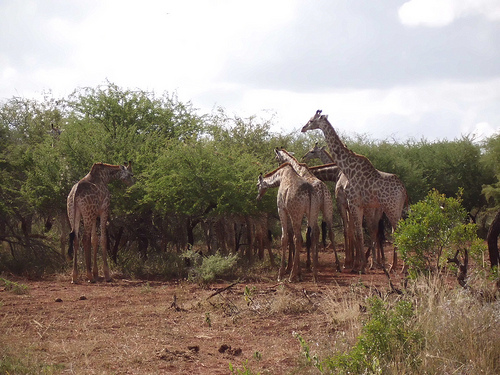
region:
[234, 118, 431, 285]
Giraffes in the wilderness.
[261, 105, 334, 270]
The giraffee is eating from tree.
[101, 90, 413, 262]
Trees around the giraffes.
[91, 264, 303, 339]
The ground is dry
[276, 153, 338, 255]
The giraffe is brown and white.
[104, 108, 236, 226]
The trees is green.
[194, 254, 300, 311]
Branches on the ground.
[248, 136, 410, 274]
Giraffes standing in a group.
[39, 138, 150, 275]
One giraffe standing alone.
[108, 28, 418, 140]
The clouds are white.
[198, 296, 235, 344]
part of a ground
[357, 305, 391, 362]
part of a plant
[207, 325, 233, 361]
part of a stone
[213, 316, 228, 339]
part of a ground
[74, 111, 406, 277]
Giraffes by the trees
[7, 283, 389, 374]
A patch of dirt in front of the giraffes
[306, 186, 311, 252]
The tail of the giraffe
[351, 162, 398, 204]
The giraffe has brown and white spots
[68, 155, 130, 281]
A giraffe eating leaves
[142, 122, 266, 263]
Trees near the giraffes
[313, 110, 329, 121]
The ears of the giraffe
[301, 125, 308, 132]
The nose of the giraffe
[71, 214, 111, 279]
The legs of the giraffe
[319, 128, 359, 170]
The giraffe has a long neck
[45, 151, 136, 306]
brown and beige giraffe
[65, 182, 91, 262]
tail on a giraffe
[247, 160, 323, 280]
brown and beige giraffe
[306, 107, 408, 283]
brown and beige giraffe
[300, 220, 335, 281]
leg of a giraffe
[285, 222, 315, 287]
leg of a giraffe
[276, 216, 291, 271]
leg on a giraffe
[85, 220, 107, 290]
leg of a giraffe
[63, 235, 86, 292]
leg of a giraffe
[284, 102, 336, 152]
face of a giraffe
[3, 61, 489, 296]
giraffes in front of row of trees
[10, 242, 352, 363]
brown dirt with branches and yellow growth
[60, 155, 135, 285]
giraffe with angle and curve on back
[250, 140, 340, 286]
giraffes with necks bent forward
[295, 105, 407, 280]
giraffe with head held up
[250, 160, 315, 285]
giraffe feeding from tree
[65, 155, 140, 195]
giraffe with head deep into tree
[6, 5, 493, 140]
light blue sky with wide white clouds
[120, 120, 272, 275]
thin and dark trunks of trees being eaten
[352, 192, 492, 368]
bush with green leaves and pale grasses